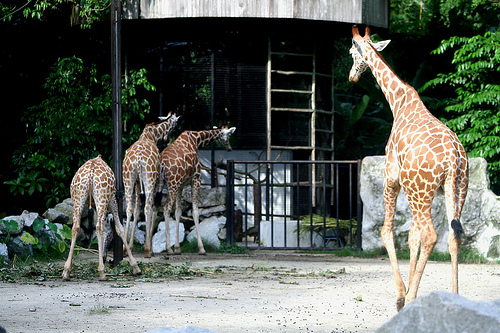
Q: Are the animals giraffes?
A: Yes, all the animals are giraffes.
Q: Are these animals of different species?
A: No, all the animals are giraffes.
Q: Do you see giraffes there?
A: Yes, there is a giraffe.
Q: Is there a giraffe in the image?
A: Yes, there is a giraffe.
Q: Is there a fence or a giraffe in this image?
A: Yes, there is a giraffe.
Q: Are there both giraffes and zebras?
A: No, there is a giraffe but no zebras.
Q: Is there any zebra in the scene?
A: No, there are no zebras.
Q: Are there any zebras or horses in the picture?
A: No, there are no zebras or horses.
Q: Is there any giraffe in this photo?
A: Yes, there is a giraffe.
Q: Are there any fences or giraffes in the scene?
A: Yes, there is a giraffe.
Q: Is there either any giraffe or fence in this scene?
A: Yes, there is a giraffe.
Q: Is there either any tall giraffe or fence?
A: Yes, there is a tall giraffe.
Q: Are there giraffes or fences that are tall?
A: Yes, the giraffe is tall.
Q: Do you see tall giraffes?
A: Yes, there is a tall giraffe.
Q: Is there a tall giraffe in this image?
A: Yes, there is a tall giraffe.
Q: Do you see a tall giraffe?
A: Yes, there is a tall giraffe.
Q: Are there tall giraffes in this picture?
A: Yes, there is a tall giraffe.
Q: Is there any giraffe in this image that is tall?
A: Yes, there is a giraffe that is tall.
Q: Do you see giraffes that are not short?
A: Yes, there is a tall giraffe.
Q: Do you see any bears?
A: No, there are no bears.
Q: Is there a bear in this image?
A: No, there are no bears.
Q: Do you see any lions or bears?
A: No, there are no bears or lions.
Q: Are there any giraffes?
A: Yes, there is a giraffe.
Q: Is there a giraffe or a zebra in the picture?
A: Yes, there is a giraffe.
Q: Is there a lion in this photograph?
A: No, there are no lions.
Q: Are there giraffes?
A: Yes, there is a giraffe.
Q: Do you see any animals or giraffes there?
A: Yes, there is a giraffe.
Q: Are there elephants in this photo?
A: No, there are no elephants.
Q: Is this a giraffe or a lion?
A: This is a giraffe.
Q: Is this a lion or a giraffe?
A: This is a giraffe.